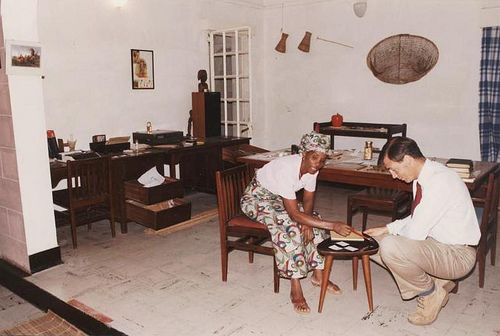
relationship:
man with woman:
[363, 138, 481, 326] [241, 133, 342, 314]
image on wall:
[130, 48, 157, 90] [42, 0, 206, 151]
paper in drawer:
[136, 165, 167, 188] [122, 168, 183, 205]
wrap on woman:
[296, 132, 332, 157] [241, 133, 342, 314]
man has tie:
[363, 138, 481, 326] [407, 181, 425, 218]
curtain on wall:
[478, 26, 499, 165] [266, 1, 500, 162]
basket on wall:
[367, 32, 440, 85] [266, 1, 500, 162]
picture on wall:
[3, 39, 46, 76] [42, 0, 206, 151]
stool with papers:
[319, 230, 381, 313] [332, 239, 361, 254]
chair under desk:
[53, 153, 119, 250] [49, 134, 250, 233]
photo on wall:
[7, 41, 40, 76] [42, 0, 206, 151]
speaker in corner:
[192, 90, 222, 137] [172, 14, 232, 165]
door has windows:
[209, 23, 253, 141] [224, 53, 238, 100]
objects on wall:
[270, 26, 318, 57] [42, 0, 206, 151]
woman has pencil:
[241, 133, 342, 314] [349, 227, 377, 245]